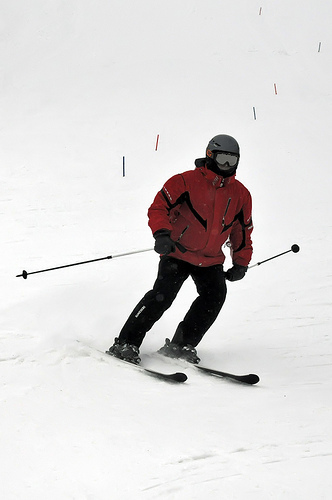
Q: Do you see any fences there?
A: No, there are no fences.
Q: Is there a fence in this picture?
A: No, there are no fences.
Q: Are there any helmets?
A: Yes, there is a helmet.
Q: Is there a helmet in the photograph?
A: Yes, there is a helmet.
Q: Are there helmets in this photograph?
A: Yes, there is a helmet.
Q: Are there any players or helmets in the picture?
A: Yes, there is a helmet.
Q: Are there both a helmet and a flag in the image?
A: No, there is a helmet but no flags.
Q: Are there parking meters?
A: No, there are no parking meters.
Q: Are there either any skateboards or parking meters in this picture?
A: No, there are no parking meters or skateboards.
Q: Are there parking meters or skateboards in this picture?
A: No, there are no parking meters or skateboards.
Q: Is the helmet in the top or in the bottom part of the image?
A: The helmet is in the top of the image.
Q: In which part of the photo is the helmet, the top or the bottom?
A: The helmet is in the top of the image.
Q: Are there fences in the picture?
A: No, there are no fences.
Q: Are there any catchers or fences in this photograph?
A: No, there are no fences or catchers.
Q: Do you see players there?
A: No, there are no players.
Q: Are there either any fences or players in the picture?
A: No, there are no players or fences.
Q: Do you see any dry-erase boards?
A: No, there are no dry-erase boards.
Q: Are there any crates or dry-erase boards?
A: No, there are no dry-erase boards or crates.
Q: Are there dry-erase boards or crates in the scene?
A: No, there are no dry-erase boards or crates.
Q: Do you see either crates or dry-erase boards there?
A: No, there are no dry-erase boards or crates.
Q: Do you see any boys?
A: No, there are no boys.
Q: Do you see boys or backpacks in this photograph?
A: No, there are no boys or backpacks.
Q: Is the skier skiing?
A: Yes, the skier is skiing.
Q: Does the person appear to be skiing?
A: Yes, the skier is skiing.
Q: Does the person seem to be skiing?
A: Yes, the skier is skiing.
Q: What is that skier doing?
A: The skier is skiing.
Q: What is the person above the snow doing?
A: The skier is skiing.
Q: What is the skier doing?
A: The skier is skiing.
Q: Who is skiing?
A: The skier is skiing.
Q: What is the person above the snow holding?
A: The skier is holding the pole.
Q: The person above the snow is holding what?
A: The skier is holding the pole.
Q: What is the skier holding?
A: The skier is holding the pole.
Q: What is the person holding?
A: The skier is holding the pole.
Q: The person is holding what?
A: The skier is holding the pole.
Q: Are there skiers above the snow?
A: Yes, there is a skier above the snow.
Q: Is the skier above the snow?
A: Yes, the skier is above the snow.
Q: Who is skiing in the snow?
A: The skier is skiing in the snow.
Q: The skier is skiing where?
A: The skier is skiing in the snow.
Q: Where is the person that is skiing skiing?
A: The skier is skiing in the snow.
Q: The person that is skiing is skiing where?
A: The skier is skiing in the snow.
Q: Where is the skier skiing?
A: The skier is skiing in the snow.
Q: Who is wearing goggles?
A: The skier is wearing goggles.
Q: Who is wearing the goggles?
A: The skier is wearing goggles.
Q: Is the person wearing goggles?
A: Yes, the skier is wearing goggles.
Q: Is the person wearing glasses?
A: No, the skier is wearing goggles.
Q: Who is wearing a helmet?
A: The skier is wearing a helmet.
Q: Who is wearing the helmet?
A: The skier is wearing a helmet.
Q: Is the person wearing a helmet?
A: Yes, the skier is wearing a helmet.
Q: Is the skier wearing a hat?
A: No, the skier is wearing a helmet.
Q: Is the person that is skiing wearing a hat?
A: No, the skier is wearing a helmet.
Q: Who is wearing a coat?
A: The skier is wearing a coat.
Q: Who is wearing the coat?
A: The skier is wearing a coat.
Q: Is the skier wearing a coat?
A: Yes, the skier is wearing a coat.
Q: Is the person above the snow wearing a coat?
A: Yes, the skier is wearing a coat.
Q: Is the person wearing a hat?
A: No, the skier is wearing a coat.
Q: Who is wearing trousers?
A: The skier is wearing trousers.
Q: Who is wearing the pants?
A: The skier is wearing trousers.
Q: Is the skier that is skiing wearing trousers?
A: Yes, the skier is wearing trousers.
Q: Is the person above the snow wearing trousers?
A: Yes, the skier is wearing trousers.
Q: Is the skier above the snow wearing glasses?
A: No, the skier is wearing trousers.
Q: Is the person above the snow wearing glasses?
A: No, the skier is wearing trousers.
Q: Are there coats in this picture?
A: Yes, there is a coat.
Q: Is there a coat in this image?
A: Yes, there is a coat.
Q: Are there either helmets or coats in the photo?
A: Yes, there is a coat.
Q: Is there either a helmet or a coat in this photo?
A: Yes, there is a coat.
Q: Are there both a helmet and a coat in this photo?
A: Yes, there are both a coat and a helmet.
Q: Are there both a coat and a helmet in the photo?
A: Yes, there are both a coat and a helmet.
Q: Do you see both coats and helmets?
A: Yes, there are both a coat and a helmet.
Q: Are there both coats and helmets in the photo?
A: Yes, there are both a coat and a helmet.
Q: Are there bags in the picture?
A: No, there are no bags.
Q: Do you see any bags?
A: No, there are no bags.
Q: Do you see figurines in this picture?
A: No, there are no figurines.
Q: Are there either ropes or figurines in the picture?
A: No, there are no figurines or ropes.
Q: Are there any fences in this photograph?
A: No, there are no fences.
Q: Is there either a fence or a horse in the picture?
A: No, there are no fences or horses.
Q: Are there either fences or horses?
A: No, there are no fences or horses.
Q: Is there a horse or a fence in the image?
A: No, there are no fences or horses.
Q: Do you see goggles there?
A: Yes, there are goggles.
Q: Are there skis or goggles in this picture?
A: Yes, there are goggles.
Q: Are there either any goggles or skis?
A: Yes, there are goggles.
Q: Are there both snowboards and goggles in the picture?
A: No, there are goggles but no snowboards.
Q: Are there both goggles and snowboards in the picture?
A: No, there are goggles but no snowboards.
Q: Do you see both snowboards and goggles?
A: No, there are goggles but no snowboards.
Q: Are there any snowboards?
A: No, there are no snowboards.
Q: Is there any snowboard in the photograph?
A: No, there are no snowboards.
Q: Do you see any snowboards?
A: No, there are no snowboards.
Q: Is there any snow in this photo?
A: Yes, there is snow.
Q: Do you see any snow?
A: Yes, there is snow.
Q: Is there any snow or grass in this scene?
A: Yes, there is snow.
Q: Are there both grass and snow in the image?
A: No, there is snow but no grass.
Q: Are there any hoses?
A: No, there are no hoses.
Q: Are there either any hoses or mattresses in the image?
A: No, there are no hoses or mattresses.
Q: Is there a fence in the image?
A: No, there are no fences.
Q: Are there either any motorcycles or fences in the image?
A: No, there are no fences or motorcycles.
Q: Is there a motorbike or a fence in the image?
A: No, there are no fences or motorcycles.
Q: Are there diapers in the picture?
A: No, there are no diapers.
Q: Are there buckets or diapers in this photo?
A: No, there are no diapers or buckets.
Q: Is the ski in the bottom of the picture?
A: Yes, the ski is in the bottom of the image.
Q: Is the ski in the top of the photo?
A: No, the ski is in the bottom of the image.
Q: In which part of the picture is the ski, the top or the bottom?
A: The ski is in the bottom of the image.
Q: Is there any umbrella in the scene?
A: No, there are no umbrellas.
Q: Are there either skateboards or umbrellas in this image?
A: No, there are no umbrellas or skateboards.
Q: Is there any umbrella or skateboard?
A: No, there are no umbrellas or skateboards.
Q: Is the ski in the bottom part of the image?
A: Yes, the ski is in the bottom of the image.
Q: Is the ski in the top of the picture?
A: No, the ski is in the bottom of the image.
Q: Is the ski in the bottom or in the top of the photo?
A: The ski is in the bottom of the image.